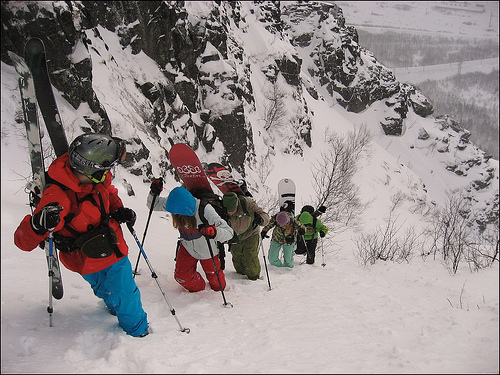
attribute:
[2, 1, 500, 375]
mountain — rocky, steep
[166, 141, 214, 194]
snowboard — red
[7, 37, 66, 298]
skis — black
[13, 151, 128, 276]
parka — red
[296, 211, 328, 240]
coat — green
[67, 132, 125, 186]
helmet — black, silver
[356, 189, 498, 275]
branches — bare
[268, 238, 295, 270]
pants — green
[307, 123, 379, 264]
brush — leafless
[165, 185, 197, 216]
hood — blue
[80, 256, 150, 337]
pants — blue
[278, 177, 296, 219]
snowboard — white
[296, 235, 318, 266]
pants — black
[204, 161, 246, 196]
board — red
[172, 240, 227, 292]
pants — red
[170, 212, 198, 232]
hair — long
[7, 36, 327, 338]
skiers — climbing